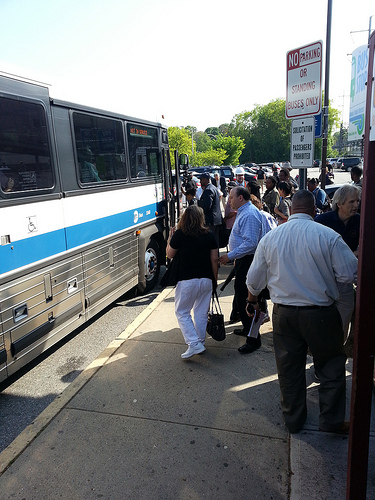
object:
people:
[166, 184, 361, 436]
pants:
[174, 277, 212, 359]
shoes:
[181, 342, 205, 359]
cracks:
[61, 403, 294, 445]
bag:
[205, 287, 226, 342]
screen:
[129, 126, 155, 136]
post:
[290, 117, 314, 167]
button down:
[237, 213, 239, 216]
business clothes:
[245, 189, 358, 435]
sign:
[348, 45, 368, 141]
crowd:
[165, 162, 364, 434]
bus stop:
[0, 204, 375, 499]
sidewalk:
[0, 378, 283, 499]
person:
[166, 204, 219, 359]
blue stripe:
[83, 225, 116, 235]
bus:
[0, 71, 190, 389]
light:
[66, 277, 78, 295]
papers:
[247, 309, 265, 338]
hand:
[246, 302, 260, 317]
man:
[215, 184, 264, 354]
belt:
[235, 254, 255, 261]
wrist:
[228, 251, 236, 260]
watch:
[228, 253, 232, 261]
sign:
[285, 39, 322, 119]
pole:
[320, 1, 332, 193]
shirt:
[244, 212, 359, 308]